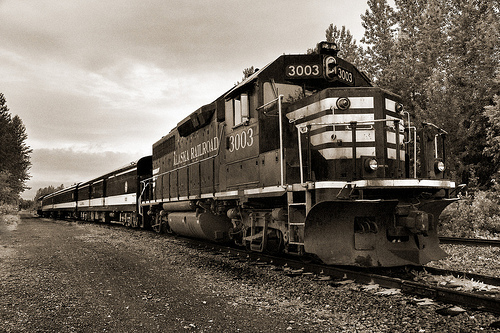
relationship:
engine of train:
[145, 38, 470, 270] [32, 39, 457, 276]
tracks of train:
[359, 264, 499, 329] [32, 39, 457, 276]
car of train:
[75, 146, 147, 230] [32, 39, 457, 276]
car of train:
[32, 179, 78, 221] [32, 39, 457, 276]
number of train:
[224, 124, 256, 156] [32, 39, 457, 276]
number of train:
[287, 61, 321, 78] [32, 39, 457, 276]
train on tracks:
[32, 39, 457, 276] [359, 264, 499, 329]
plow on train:
[301, 195, 463, 271] [32, 39, 457, 276]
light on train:
[359, 155, 381, 181] [32, 39, 457, 276]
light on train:
[434, 159, 452, 176] [32, 39, 457, 276]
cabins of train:
[34, 152, 153, 228] [32, 39, 457, 276]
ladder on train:
[281, 183, 320, 252] [32, 39, 457, 276]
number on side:
[224, 124, 256, 156] [146, 53, 285, 204]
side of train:
[146, 53, 285, 204] [32, 39, 457, 276]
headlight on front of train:
[320, 39, 343, 82] [32, 39, 457, 276]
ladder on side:
[281, 183, 320, 252] [146, 53, 285, 204]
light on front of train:
[359, 155, 381, 181] [32, 39, 457, 276]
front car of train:
[75, 146, 147, 230] [32, 39, 457, 276]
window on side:
[231, 93, 255, 128] [146, 53, 285, 204]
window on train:
[260, 78, 308, 114] [32, 39, 457, 276]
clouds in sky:
[1, 69, 141, 178] [2, 0, 367, 129]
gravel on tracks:
[343, 292, 489, 332] [359, 264, 499, 329]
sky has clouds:
[2, 0, 367, 129] [1, 69, 141, 178]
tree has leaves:
[1, 95, 31, 228] [4, 119, 25, 170]